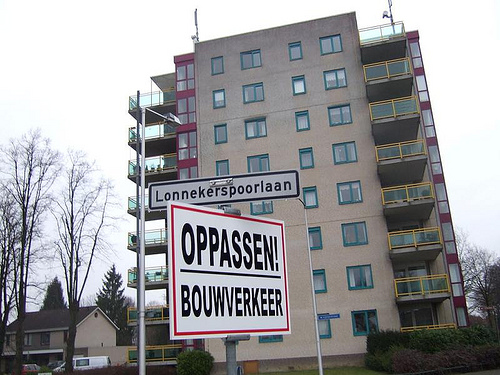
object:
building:
[128, 0, 470, 374]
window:
[238, 48, 263, 73]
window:
[241, 82, 265, 105]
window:
[243, 116, 267, 141]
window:
[290, 73, 307, 96]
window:
[294, 109, 312, 132]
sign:
[166, 201, 290, 340]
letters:
[180, 222, 284, 317]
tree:
[39, 147, 129, 374]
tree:
[0, 125, 62, 374]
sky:
[0, 0, 500, 318]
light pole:
[138, 106, 183, 374]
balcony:
[127, 89, 178, 128]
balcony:
[127, 120, 178, 158]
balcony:
[128, 151, 178, 187]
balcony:
[358, 21, 408, 65]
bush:
[366, 326, 499, 372]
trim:
[295, 109, 312, 132]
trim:
[297, 145, 316, 171]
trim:
[361, 55, 413, 83]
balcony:
[361, 57, 412, 104]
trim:
[367, 96, 422, 123]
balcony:
[368, 96, 422, 146]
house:
[1, 305, 130, 371]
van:
[51, 355, 109, 374]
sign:
[145, 168, 300, 210]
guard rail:
[393, 273, 450, 299]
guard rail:
[385, 226, 442, 251]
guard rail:
[380, 181, 434, 207]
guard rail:
[374, 137, 431, 163]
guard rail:
[129, 344, 181, 362]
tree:
[453, 227, 499, 325]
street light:
[144, 108, 182, 128]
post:
[224, 336, 250, 374]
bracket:
[209, 177, 233, 187]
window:
[209, 55, 225, 76]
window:
[286, 40, 302, 61]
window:
[317, 32, 344, 56]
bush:
[174, 348, 215, 374]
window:
[312, 267, 329, 293]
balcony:
[375, 139, 427, 188]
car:
[20, 362, 43, 374]